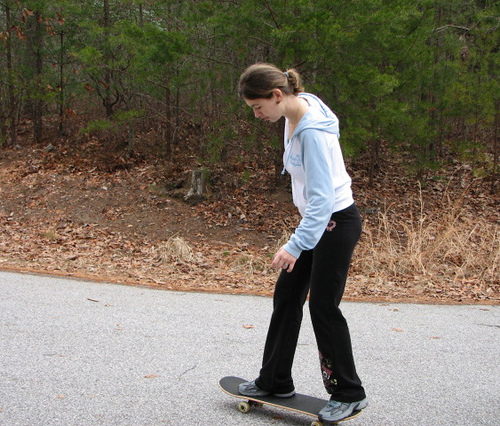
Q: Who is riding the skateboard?
A: The woman.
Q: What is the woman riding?
A: Skateboard.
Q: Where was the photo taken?
A: The street.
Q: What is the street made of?
A: Cement.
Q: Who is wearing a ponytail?
A: Tall woman.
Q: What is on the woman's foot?
A: Sneakers.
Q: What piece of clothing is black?
A: Black skate pants.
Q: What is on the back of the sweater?
A: Hoodie.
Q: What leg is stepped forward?
A: Right leg.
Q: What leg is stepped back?
A: Left leg.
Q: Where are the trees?
A: Behind the path.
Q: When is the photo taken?
A: Daytime.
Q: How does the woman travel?
A: By skateboard.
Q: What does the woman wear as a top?
A: A hoodie.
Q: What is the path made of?
A: Asphalt.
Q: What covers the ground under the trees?
A: Dead leaves.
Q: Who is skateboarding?
A: A woman.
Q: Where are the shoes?
A: On the woman's feet.